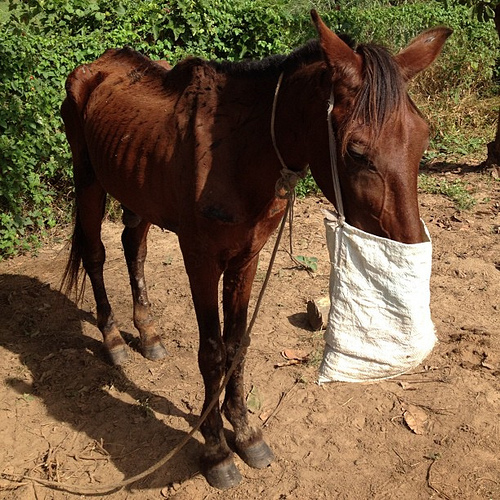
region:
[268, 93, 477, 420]
White feed bag on horse.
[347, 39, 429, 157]
Brown hair on horse's head.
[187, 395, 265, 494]
Hooves on horse's foot.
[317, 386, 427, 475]
Dirt on the ground.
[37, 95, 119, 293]
Brown tail on horse.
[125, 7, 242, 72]
Green leaves behind horse.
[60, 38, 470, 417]
Brown horse eating.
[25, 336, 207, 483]
Rope on horse's head.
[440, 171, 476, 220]
Green grass in the dirt.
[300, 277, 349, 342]
Rock in the dirt.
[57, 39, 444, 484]
Small horse feeding time.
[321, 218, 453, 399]
Food feed bag over snout.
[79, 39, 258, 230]
Poor horse severely malnourished.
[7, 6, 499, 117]
Green foliage behind animal.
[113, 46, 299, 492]
Lead rope around neck.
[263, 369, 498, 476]
Dry brown dusty soil.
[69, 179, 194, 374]
Hind legs strength lacking.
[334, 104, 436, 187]
Eyes downtrodden ill appearance.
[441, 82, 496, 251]
Appears sparse green growth.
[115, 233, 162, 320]
Sores left rear leg.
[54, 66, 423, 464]
One horse is seen.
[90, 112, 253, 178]
horse in brown color.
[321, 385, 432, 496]
Ground is brown color.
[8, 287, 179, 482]
shadow falls in ground.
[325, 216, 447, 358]
White bag is tied to horse mouth.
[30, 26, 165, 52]
Bushes are green color.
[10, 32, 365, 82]
Bushes are seen behind the horse.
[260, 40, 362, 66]
Hairs in horse are brown color.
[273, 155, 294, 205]
Rope is white color.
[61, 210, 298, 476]
Four legs for horse.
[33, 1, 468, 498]
Horse is brown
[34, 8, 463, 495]
Horse is thin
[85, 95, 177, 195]
Ribs of horse can be seen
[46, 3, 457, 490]
Horse has a white bag on his muzzle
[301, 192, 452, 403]
White bag on muzzle of horse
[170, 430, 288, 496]
Hooves of horse are black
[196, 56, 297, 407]
Rope tie in neck of horse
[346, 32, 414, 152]
Mane of horse on front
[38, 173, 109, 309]
Tail of horse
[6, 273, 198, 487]
Shadow of horse cast on the grownd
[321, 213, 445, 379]
the feed bag that the horse is eating from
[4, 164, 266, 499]
the rope holding the horse in place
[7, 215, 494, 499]
the ground the horse is standing on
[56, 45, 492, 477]
a thin brown horse eating food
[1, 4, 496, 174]
a hedge that is behind the horse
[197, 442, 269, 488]
the front hooves of the horse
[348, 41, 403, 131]
the black mane of the horse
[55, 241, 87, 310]
the tail of the horse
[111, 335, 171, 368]
the back hooves of the horse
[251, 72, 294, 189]
a rope around the horse's neck